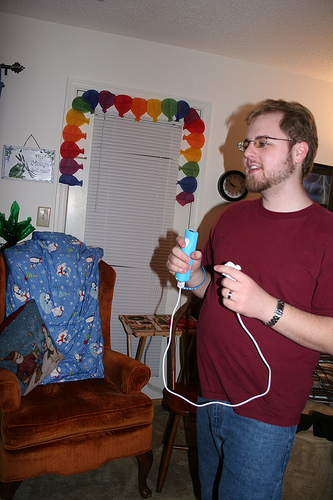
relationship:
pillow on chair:
[2, 298, 64, 397] [1, 258, 154, 500]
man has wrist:
[166, 98, 332, 499] [262, 294, 294, 334]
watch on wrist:
[264, 298, 285, 328] [262, 294, 294, 334]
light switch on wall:
[35, 205, 52, 228] [1, 13, 332, 388]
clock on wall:
[217, 169, 249, 203] [1, 13, 332, 388]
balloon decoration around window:
[60, 89, 206, 208] [55, 75, 212, 396]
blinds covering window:
[85, 111, 180, 376] [55, 75, 212, 396]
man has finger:
[166, 98, 332, 499] [219, 286, 239, 302]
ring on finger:
[226, 289, 236, 302] [219, 286, 239, 302]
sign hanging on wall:
[3, 149, 58, 184] [1, 13, 332, 388]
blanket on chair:
[3, 229, 106, 384] [1, 258, 154, 500]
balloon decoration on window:
[60, 89, 206, 208] [55, 75, 212, 396]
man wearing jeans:
[166, 98, 332, 499] [194, 395, 298, 499]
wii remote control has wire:
[161, 230, 272, 409] [161, 284, 271, 410]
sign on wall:
[3, 149, 58, 184] [1, 13, 332, 388]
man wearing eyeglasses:
[166, 98, 332, 499] [237, 134, 298, 148]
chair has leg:
[1, 258, 154, 500] [135, 449, 156, 500]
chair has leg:
[1, 258, 154, 500] [1, 479, 26, 499]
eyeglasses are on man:
[237, 134, 298, 148] [166, 98, 332, 499]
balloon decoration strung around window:
[60, 89, 206, 208] [55, 75, 212, 396]